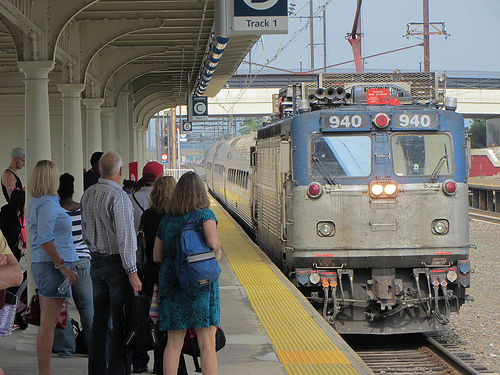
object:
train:
[204, 80, 474, 338]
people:
[151, 169, 222, 375]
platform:
[0, 190, 378, 375]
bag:
[174, 224, 222, 292]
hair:
[168, 171, 211, 216]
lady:
[26, 160, 79, 375]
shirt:
[25, 196, 80, 264]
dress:
[155, 207, 220, 332]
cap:
[142, 161, 164, 180]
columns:
[22, 61, 52, 307]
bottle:
[57, 271, 78, 294]